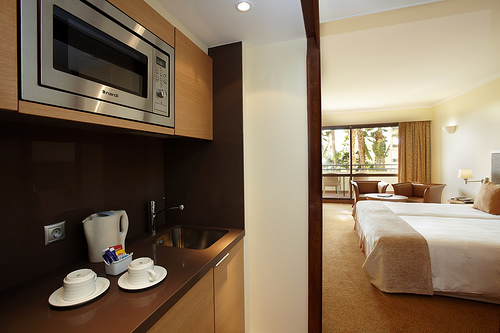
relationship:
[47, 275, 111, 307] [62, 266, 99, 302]
saucer under mug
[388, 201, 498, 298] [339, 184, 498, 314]
bedspread on bed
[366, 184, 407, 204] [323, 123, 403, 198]
table near window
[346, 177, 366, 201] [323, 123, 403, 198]
chairs near window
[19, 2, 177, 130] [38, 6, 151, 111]
metal microwave with a door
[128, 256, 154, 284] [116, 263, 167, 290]
cup on a plate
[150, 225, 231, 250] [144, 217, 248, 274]
sink at countertop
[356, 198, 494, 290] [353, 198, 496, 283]
blanket at bed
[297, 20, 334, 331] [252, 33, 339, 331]
framing on a wall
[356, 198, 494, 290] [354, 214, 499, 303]
blanket on a bed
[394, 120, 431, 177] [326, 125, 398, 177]
curtain on window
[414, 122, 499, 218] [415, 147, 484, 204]
wall beside lamp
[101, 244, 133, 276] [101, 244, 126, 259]
holder containing packets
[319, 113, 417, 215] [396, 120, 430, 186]
window with curtain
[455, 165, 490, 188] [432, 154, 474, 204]
lamp with shade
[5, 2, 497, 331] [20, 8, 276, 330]
hotel room has a mini kitchen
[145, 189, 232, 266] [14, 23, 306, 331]
sink in mini kitchen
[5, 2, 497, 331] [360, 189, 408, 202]
hotel room has table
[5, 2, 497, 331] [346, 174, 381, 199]
hotel room has chair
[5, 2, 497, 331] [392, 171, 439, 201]
hotel room has chair